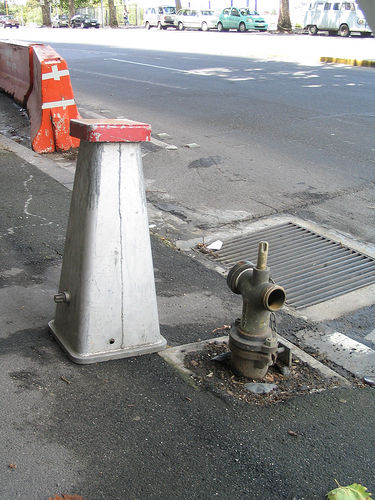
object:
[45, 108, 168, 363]
cone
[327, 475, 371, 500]
leaf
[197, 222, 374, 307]
storm grate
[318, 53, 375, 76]
stripe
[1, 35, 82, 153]
barriers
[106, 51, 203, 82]
stripe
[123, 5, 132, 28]
person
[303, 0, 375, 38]
bus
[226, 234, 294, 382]
water hydrant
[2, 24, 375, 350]
road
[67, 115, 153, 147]
top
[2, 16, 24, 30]
car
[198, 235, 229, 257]
garbage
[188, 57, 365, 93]
shadows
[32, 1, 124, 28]
trees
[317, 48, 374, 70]
curb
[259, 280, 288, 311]
hose attachment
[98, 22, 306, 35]
sidewalk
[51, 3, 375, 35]
six vehicles